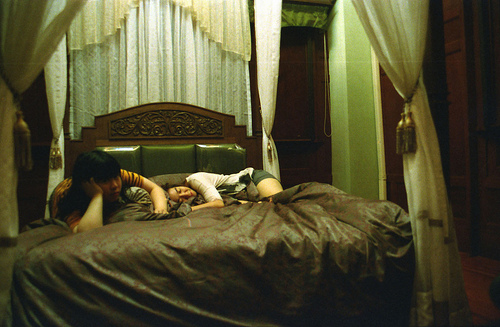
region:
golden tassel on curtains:
[388, 99, 415, 156]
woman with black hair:
[48, 146, 142, 231]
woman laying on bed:
[155, 158, 292, 228]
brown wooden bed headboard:
[75, 96, 249, 143]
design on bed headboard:
[110, 111, 227, 138]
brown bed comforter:
[33, 225, 368, 310]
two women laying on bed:
[33, 128, 298, 247]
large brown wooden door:
[285, 37, 320, 177]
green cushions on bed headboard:
[132, 143, 229, 170]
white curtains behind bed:
[93, 1, 231, 97]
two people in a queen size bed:
[8, 103, 419, 317]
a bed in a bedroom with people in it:
[3, 3, 497, 324]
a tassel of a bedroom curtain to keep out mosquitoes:
[386, 79, 438, 165]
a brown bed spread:
[26, 169, 411, 325]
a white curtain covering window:
[53, 0, 260, 147]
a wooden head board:
[71, 94, 246, 151]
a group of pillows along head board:
[101, 137, 244, 172]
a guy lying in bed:
[24, 140, 171, 227]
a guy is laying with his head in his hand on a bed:
[44, 141, 171, 235]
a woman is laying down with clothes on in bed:
[170, 153, 290, 211]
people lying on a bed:
[37, 129, 316, 237]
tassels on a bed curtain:
[374, 74, 439, 158]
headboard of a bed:
[57, 95, 264, 171]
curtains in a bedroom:
[60, 0, 253, 123]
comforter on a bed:
[19, 229, 410, 307]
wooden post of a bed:
[236, 2, 277, 132]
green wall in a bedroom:
[338, 20, 371, 181]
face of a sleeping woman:
[156, 175, 203, 208]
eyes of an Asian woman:
[97, 168, 127, 183]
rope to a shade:
[319, 27, 341, 144]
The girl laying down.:
[165, 169, 281, 214]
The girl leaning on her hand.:
[59, 157, 165, 229]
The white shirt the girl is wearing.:
[184, 166, 254, 188]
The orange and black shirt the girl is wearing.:
[57, 174, 150, 236]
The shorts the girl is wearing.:
[249, 163, 277, 184]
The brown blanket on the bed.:
[30, 217, 422, 303]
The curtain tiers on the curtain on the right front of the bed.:
[384, 62, 433, 155]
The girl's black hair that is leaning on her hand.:
[54, 145, 137, 214]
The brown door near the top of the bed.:
[280, 19, 332, 184]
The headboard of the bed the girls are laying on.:
[60, 98, 263, 181]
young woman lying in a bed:
[41, 149, 170, 233]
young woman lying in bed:
[163, 169, 303, 214]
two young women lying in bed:
[47, 142, 285, 324]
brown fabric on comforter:
[13, 228, 402, 320]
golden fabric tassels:
[395, 95, 418, 151]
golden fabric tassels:
[47, 134, 62, 170]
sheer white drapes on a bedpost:
[343, 0, 463, 323]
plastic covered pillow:
[141, 142, 193, 170]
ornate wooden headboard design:
[103, 105, 225, 137]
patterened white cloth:
[69, 2, 248, 109]